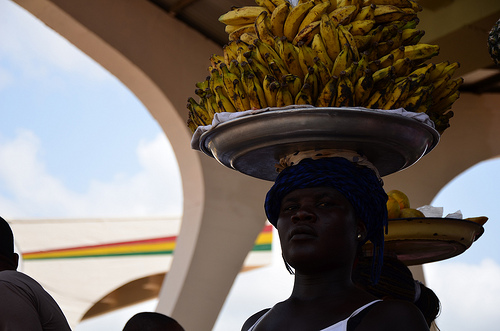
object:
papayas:
[378, 185, 432, 216]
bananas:
[185, 0, 465, 131]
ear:
[356, 218, 366, 242]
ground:
[435, 159, 476, 192]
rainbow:
[17, 220, 277, 260]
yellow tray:
[361, 215, 485, 264]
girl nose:
[291, 208, 318, 221]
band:
[21, 223, 274, 261]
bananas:
[386, 187, 426, 220]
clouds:
[0, 0, 185, 220]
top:
[234, 287, 409, 330]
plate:
[383, 212, 485, 267]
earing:
[357, 233, 365, 242]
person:
[240, 147, 429, 330]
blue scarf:
[264, 153, 391, 234]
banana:
[223, 71, 250, 112]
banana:
[210, 70, 231, 110]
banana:
[309, 33, 333, 69]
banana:
[331, 46, 349, 76]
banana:
[253, 9, 277, 43]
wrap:
[260, 154, 387, 232]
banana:
[269, 1, 289, 36]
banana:
[283, 0, 314, 44]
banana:
[297, 0, 330, 31]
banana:
[218, 8, 271, 26]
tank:
[242, 282, 377, 330]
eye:
[318, 198, 335, 209]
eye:
[281, 201, 296, 214]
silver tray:
[196, 110, 441, 170]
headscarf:
[262, 159, 387, 219]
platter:
[191, 71, 463, 176]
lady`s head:
[263, 154, 385, 277]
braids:
[360, 254, 441, 329]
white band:
[412, 280, 421, 305]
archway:
[0, 0, 275, 330]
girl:
[237, 146, 438, 330]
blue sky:
[32, 89, 111, 150]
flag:
[20, 228, 281, 272]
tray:
[197, 103, 415, 173]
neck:
[288, 264, 364, 301]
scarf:
[263, 157, 391, 209]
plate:
[198, 103, 440, 182]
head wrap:
[262, 163, 385, 218]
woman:
[239, 158, 436, 331]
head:
[262, 162, 381, 272]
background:
[0, 0, 499, 330]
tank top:
[243, 288, 393, 330]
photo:
[4, 6, 499, 330]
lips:
[282, 220, 327, 246]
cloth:
[190, 104, 432, 151]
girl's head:
[261, 159, 387, 279]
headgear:
[263, 150, 393, 275]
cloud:
[0, 109, 189, 222]